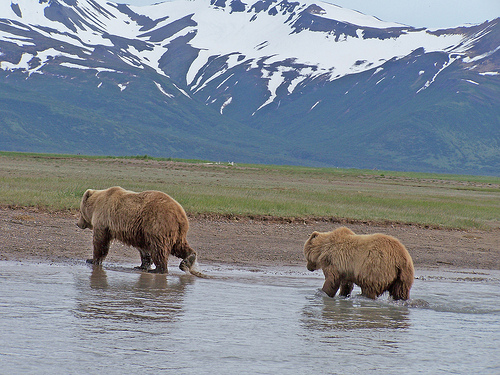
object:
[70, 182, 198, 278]
bear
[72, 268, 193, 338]
bear reflection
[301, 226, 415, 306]
bear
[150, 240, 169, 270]
leg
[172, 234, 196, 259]
leg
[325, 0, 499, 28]
blue sky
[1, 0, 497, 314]
landscape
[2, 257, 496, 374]
water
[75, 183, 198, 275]
bears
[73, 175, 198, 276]
bears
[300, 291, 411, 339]
reflection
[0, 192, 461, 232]
edge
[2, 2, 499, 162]
mountain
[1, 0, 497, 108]
snow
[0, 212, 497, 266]
dirt shore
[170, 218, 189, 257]
tail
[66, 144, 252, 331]
bear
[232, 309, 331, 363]
part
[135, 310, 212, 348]
part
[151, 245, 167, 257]
part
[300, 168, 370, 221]
part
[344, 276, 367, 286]
belly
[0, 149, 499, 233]
grass